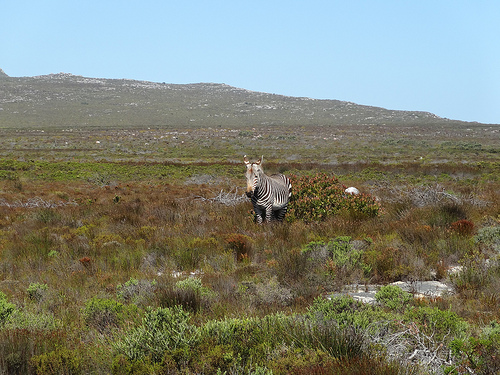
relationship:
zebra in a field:
[239, 152, 298, 224] [1, 156, 498, 374]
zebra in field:
[239, 152, 298, 224] [1, 156, 498, 374]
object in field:
[344, 185, 362, 195] [1, 156, 498, 374]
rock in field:
[342, 278, 456, 305] [1, 156, 498, 374]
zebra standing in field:
[239, 152, 298, 224] [1, 156, 498, 374]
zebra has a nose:
[239, 152, 298, 224] [245, 187, 256, 199]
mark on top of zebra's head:
[248, 162, 254, 178] [239, 154, 269, 202]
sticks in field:
[370, 322, 462, 373] [1, 156, 498, 374]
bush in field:
[277, 168, 380, 223] [1, 156, 498, 374]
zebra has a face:
[239, 152, 298, 224] [243, 164, 262, 199]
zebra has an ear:
[239, 152, 298, 224] [241, 153, 250, 168]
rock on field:
[342, 278, 456, 305] [1, 156, 498, 374]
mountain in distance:
[1, 73, 466, 130] [1, 1, 499, 181]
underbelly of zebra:
[272, 201, 285, 213] [239, 152, 298, 224]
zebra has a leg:
[239, 152, 298, 224] [262, 205, 272, 225]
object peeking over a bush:
[344, 185, 362, 195] [277, 168, 380, 223]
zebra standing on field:
[239, 152, 298, 224] [1, 156, 498, 374]